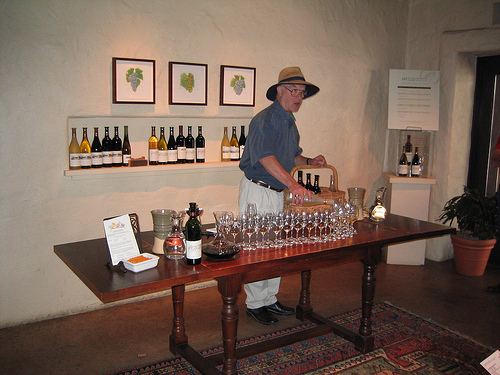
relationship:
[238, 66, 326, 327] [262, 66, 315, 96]
man in hat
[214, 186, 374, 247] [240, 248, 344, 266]
glasses in table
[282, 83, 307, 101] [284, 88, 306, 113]
glasses on face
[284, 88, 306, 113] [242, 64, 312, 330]
face on man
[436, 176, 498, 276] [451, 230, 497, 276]
plant in planter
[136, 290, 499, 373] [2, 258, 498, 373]
carpet on floor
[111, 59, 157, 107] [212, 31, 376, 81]
poster on wall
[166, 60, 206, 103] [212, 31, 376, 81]
poster on wall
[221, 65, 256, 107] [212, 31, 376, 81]
poster on wall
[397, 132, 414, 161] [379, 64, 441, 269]
bottle on stand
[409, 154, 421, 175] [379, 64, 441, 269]
bottle on stand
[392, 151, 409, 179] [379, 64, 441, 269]
bottle on stand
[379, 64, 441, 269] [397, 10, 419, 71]
stand at corner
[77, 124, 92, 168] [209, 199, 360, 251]
beverage poured in glasses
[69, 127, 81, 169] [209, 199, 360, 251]
beverage poured in glasses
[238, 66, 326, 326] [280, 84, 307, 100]
man wearing glasses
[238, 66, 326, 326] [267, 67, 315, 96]
man wearing hat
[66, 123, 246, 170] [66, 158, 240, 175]
wine bottles on shelf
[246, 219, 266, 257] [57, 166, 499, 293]
wine glass on table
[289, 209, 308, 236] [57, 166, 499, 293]
wine glass on table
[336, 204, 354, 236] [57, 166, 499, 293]
wine glass on table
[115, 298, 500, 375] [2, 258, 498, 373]
carpet on floor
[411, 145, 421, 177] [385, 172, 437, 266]
bottle on pedestal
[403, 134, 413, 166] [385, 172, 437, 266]
bottle on pedestal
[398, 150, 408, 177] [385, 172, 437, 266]
bottle on pedestal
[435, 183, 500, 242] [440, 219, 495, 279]
plant in planter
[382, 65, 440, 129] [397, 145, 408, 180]
poster above wine bottle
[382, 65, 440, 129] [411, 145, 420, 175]
poster above wine bottle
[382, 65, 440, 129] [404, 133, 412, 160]
poster above wine bottle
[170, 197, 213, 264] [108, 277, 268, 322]
wine on table